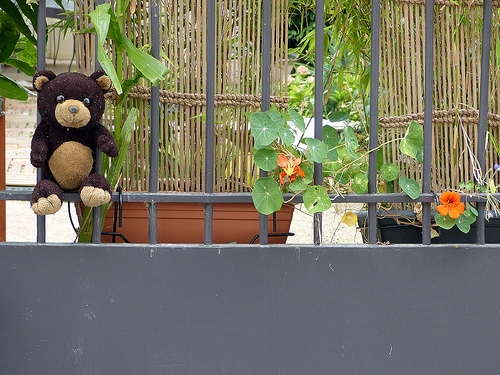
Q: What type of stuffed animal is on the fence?
A: Teddy bear.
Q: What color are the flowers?
A: Orange.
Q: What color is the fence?
A: Gray.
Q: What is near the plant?
A: Bear.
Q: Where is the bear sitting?
A: Fence.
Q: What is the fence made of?
A: Metal.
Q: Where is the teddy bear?
A: Fence.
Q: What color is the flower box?
A: Brown.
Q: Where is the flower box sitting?
A: Ledge.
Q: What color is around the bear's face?
A: Tan.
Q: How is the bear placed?
A: In the grey bars.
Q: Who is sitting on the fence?
A: A stuffed bear.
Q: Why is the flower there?
A: It is growing towards the sun.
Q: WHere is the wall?
A: Under the fence.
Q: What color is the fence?
A: Gray.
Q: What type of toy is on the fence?
A: A teddy bear.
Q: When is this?
A: Daytime.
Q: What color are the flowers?
A: Orange.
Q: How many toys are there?
A: One.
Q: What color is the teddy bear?
A: Brown.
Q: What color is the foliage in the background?
A: Green.